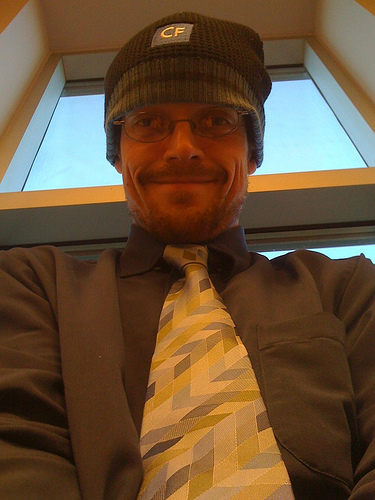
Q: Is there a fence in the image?
A: No, there are no fences.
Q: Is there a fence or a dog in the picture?
A: No, there are no fences or dogs.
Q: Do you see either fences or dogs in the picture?
A: No, there are no fences or dogs.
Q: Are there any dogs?
A: No, there are no dogs.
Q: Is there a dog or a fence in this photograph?
A: No, there are no dogs or fences.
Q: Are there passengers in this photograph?
A: No, there are no passengers.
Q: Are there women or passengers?
A: No, there are no passengers or women.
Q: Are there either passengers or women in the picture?
A: No, there are no passengers or women.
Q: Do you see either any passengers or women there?
A: No, there are no passengers or women.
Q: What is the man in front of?
A: The man is in front of the window.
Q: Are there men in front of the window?
A: Yes, there is a man in front of the window.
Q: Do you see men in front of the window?
A: Yes, there is a man in front of the window.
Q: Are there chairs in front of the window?
A: No, there is a man in front of the window.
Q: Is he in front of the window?
A: Yes, the man is in front of the window.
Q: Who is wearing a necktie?
A: The man is wearing a necktie.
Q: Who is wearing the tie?
A: The man is wearing a necktie.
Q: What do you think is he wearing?
A: The man is wearing a necktie.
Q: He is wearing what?
A: The man is wearing a necktie.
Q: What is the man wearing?
A: The man is wearing a necktie.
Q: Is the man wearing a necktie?
A: Yes, the man is wearing a necktie.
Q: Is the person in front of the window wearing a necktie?
A: Yes, the man is wearing a necktie.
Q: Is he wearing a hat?
A: No, the man is wearing a necktie.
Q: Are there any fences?
A: No, there are no fences.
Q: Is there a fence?
A: No, there are no fences.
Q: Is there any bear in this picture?
A: No, there are no bears.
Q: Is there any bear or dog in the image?
A: No, there are no bears or dogs.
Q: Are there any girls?
A: No, there are no girls.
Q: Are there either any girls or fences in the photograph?
A: No, there are no girls or fences.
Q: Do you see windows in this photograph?
A: Yes, there is a window.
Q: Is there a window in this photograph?
A: Yes, there is a window.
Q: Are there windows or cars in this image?
A: Yes, there is a window.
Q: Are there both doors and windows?
A: No, there is a window but no doors.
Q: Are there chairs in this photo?
A: No, there are no chairs.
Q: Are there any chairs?
A: No, there are no chairs.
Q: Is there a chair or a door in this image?
A: No, there are no chairs or doors.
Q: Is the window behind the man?
A: Yes, the window is behind the man.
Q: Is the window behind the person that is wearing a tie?
A: Yes, the window is behind the man.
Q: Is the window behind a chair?
A: No, the window is behind the man.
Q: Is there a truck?
A: No, there are no trucks.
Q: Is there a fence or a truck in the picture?
A: No, there are no trucks or fences.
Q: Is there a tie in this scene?
A: Yes, there is a tie.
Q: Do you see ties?
A: Yes, there is a tie.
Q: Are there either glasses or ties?
A: Yes, there is a tie.